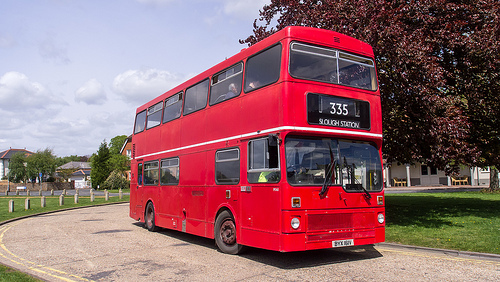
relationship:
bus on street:
[135, 66, 361, 219] [83, 227, 160, 269]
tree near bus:
[421, 39, 461, 100] [135, 66, 361, 219]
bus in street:
[135, 66, 361, 219] [83, 227, 160, 269]